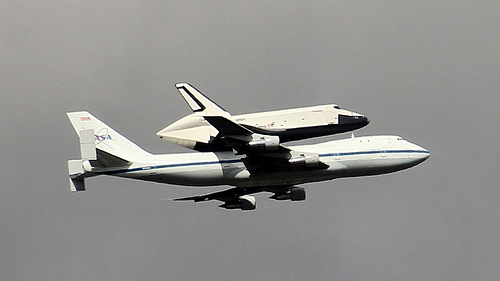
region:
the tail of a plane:
[62, 102, 146, 166]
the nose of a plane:
[410, 138, 436, 170]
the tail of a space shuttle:
[171, 74, 230, 118]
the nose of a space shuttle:
[342, 105, 377, 130]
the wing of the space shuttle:
[195, 110, 280, 145]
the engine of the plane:
[236, 133, 287, 153]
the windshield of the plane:
[393, 133, 406, 143]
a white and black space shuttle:
[158, 70, 378, 145]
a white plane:
[58, 102, 438, 214]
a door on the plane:
[376, 142, 388, 159]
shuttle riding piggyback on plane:
[51, 73, 437, 223]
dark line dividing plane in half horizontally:
[80, 140, 420, 180]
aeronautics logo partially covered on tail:
[70, 125, 120, 155]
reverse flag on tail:
[65, 100, 95, 125]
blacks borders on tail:
[165, 75, 225, 110]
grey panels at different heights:
[62, 117, 97, 193]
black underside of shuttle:
[271, 112, 371, 137]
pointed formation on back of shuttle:
[145, 110, 210, 155]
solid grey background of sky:
[50, 41, 450, 261]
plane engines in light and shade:
[246, 125, 308, 210]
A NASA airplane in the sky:
[58, 67, 444, 243]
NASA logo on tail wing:
[67, 108, 147, 169]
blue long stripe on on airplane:
[115, 130, 450, 206]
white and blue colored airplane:
[64, 105, 449, 220]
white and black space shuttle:
[135, 64, 379, 141]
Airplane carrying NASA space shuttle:
[44, 72, 446, 217]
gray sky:
[421, 29, 496, 136]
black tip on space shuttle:
[326, 92, 387, 130]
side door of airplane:
[377, 144, 397, 164]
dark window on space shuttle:
[327, 102, 354, 117]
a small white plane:
[164, 86, 358, 141]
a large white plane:
[77, 134, 445, 191]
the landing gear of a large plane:
[192, 188, 319, 214]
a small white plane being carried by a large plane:
[57, 80, 452, 210]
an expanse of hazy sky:
[19, 5, 246, 76]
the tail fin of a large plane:
[67, 107, 154, 162]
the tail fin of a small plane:
[176, 91, 226, 122]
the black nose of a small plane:
[338, 111, 362, 127]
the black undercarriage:
[239, 119, 369, 139]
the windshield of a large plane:
[394, 134, 408, 145]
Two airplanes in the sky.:
[44, 65, 447, 217]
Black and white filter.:
[2, 2, 498, 279]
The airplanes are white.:
[59, 74, 436, 214]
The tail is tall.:
[63, 106, 158, 166]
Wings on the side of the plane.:
[174, 77, 300, 234]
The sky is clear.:
[5, 2, 495, 273]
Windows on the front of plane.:
[326, 96, 344, 108]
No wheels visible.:
[237, 157, 299, 208]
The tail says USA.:
[77, 122, 112, 147]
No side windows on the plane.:
[142, 128, 419, 180]